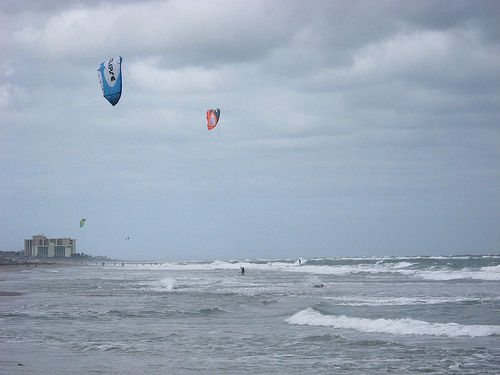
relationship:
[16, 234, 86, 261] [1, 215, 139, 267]
building in background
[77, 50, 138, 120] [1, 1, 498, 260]
kite in sky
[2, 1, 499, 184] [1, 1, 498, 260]
clouds in sky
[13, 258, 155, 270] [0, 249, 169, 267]
people on shore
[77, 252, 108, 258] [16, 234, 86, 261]
trees near building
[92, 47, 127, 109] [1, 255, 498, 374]
kite over ocean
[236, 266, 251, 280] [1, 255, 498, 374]
person in ocean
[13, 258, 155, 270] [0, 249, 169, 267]
people stand ashore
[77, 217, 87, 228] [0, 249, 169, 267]
kite above beach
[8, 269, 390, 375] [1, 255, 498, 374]
part of ocean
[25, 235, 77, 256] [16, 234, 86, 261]
section of building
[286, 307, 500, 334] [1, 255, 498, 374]
waves in ocean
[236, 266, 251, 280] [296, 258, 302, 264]
person in black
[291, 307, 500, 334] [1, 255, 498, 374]
waves in ocean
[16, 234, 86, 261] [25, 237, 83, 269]
building in distance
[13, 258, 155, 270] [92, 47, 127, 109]
people with kite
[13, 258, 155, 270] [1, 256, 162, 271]
people on beach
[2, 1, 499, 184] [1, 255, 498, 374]
clouds above ocean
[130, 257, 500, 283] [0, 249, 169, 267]
waves near shore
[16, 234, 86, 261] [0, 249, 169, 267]
building on shore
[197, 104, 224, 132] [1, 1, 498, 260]
kite in sky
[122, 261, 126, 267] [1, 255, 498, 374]
person in water